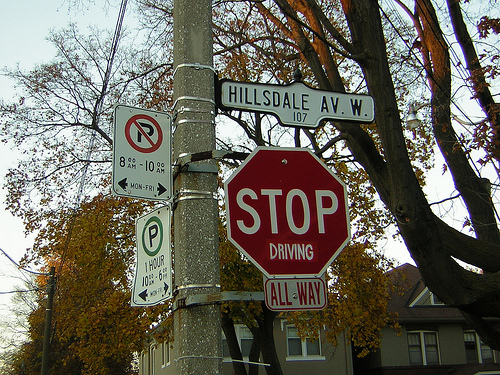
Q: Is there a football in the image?
A: No, there are no footballs.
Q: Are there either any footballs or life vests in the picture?
A: No, there are no footballs or life vests.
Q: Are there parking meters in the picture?
A: No, there are no parking meters.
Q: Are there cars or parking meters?
A: No, there are no parking meters or cars.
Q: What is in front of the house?
A: The pole is in front of the house.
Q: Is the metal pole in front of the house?
A: Yes, the pole is in front of the house.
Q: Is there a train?
A: No, there are no trains.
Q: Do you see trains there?
A: No, there are no trains.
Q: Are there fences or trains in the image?
A: No, there are no trains or fences.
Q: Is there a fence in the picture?
A: No, there are no fences.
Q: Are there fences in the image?
A: No, there are no fences.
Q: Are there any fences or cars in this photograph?
A: No, there are no fences or cars.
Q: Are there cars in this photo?
A: No, there are no cars.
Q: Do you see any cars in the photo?
A: No, there are no cars.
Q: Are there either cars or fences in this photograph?
A: No, there are no cars or fences.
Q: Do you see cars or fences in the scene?
A: No, there are no cars or fences.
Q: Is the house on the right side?
A: Yes, the house is on the right of the image.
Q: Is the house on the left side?
A: No, the house is on the right of the image.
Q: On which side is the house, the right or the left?
A: The house is on the right of the image.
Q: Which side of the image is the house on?
A: The house is on the right of the image.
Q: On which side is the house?
A: The house is on the right of the image.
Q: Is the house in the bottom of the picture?
A: Yes, the house is in the bottom of the image.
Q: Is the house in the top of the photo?
A: No, the house is in the bottom of the image.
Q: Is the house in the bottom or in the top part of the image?
A: The house is in the bottom of the image.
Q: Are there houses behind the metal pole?
A: Yes, there is a house behind the pole.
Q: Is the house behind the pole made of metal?
A: Yes, the house is behind the pole.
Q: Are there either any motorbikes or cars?
A: No, there are no cars or motorbikes.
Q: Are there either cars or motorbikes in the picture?
A: No, there are no cars or motorbikes.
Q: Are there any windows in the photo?
A: Yes, there is a window.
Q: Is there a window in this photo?
A: Yes, there is a window.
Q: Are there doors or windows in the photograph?
A: Yes, there is a window.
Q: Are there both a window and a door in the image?
A: No, there is a window but no doors.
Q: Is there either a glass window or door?
A: Yes, there is a glass window.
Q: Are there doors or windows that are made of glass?
A: Yes, the window is made of glass.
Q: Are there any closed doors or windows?
A: Yes, there is a closed window.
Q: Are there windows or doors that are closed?
A: Yes, the window is closed.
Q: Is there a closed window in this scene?
A: Yes, there is a closed window.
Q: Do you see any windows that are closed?
A: Yes, there is a window that is closed.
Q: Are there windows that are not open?
A: Yes, there is an closed window.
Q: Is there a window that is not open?
A: Yes, there is an closed window.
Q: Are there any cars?
A: No, there are no cars.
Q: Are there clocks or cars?
A: No, there are no cars or clocks.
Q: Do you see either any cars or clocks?
A: No, there are no cars or clocks.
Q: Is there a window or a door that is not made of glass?
A: No, there is a window but it is made of glass.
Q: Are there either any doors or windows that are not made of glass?
A: No, there is a window but it is made of glass.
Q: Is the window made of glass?
A: Yes, the window is made of glass.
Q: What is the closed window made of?
A: The window is made of glass.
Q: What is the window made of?
A: The window is made of glass.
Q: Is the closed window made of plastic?
A: No, the window is made of glass.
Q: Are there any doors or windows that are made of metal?
A: No, there is a window but it is made of glass.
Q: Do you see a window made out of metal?
A: No, there is a window but it is made of glass.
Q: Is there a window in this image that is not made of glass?
A: No, there is a window but it is made of glass.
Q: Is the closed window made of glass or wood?
A: The window is made of glass.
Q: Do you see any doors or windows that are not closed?
A: No, there is a window but it is closed.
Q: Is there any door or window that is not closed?
A: No, there is a window but it is closed.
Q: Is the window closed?
A: Yes, the window is closed.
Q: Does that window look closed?
A: Yes, the window is closed.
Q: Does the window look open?
A: No, the window is closed.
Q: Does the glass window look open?
A: No, the window is closed.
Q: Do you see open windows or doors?
A: No, there is a window but it is closed.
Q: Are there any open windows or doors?
A: No, there is a window but it is closed.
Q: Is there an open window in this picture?
A: No, there is a window but it is closed.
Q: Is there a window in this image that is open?
A: No, there is a window but it is closed.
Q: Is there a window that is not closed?
A: No, there is a window but it is closed.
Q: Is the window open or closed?
A: The window is closed.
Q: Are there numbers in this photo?
A: Yes, there are numbers.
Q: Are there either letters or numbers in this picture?
A: Yes, there are numbers.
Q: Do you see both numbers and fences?
A: No, there are numbers but no fences.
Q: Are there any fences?
A: No, there are no fences.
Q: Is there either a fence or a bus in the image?
A: No, there are no fences or buses.